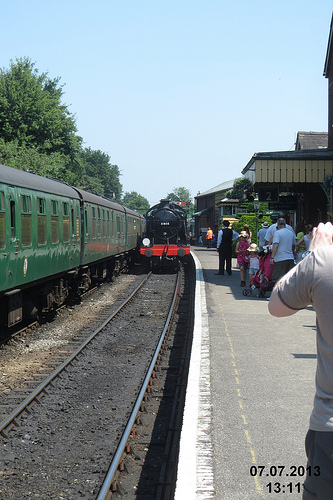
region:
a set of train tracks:
[0, 260, 181, 496]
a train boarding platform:
[173, 234, 329, 498]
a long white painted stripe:
[173, 245, 214, 496]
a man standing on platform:
[212, 219, 237, 272]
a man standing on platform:
[269, 217, 293, 283]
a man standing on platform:
[265, 223, 330, 497]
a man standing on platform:
[203, 226, 214, 246]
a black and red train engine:
[140, 198, 191, 274]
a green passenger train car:
[4, 163, 78, 337]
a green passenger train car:
[82, 188, 127, 289]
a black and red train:
[119, 178, 204, 295]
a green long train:
[0, 157, 166, 339]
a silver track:
[0, 246, 186, 498]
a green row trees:
[0, 45, 152, 228]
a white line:
[169, 237, 220, 497]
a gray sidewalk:
[208, 230, 330, 498]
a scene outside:
[17, 8, 328, 498]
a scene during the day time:
[14, 15, 327, 498]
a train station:
[190, 115, 331, 326]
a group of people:
[201, 209, 332, 317]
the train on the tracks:
[135, 175, 190, 283]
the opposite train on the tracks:
[0, 163, 138, 274]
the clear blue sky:
[147, 31, 228, 83]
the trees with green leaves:
[4, 75, 81, 171]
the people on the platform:
[218, 212, 328, 330]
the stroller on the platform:
[228, 246, 273, 295]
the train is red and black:
[139, 195, 184, 255]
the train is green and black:
[7, 165, 124, 268]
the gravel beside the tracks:
[0, 249, 158, 393]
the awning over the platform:
[236, 141, 331, 193]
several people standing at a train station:
[213, 199, 325, 308]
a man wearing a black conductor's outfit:
[214, 218, 240, 276]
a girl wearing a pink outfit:
[231, 229, 253, 290]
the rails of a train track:
[66, 286, 172, 488]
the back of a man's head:
[272, 215, 289, 233]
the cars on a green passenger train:
[13, 174, 138, 264]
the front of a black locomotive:
[135, 197, 196, 274]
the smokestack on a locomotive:
[158, 197, 172, 212]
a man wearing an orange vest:
[202, 225, 214, 248]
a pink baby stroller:
[240, 249, 270, 299]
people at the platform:
[208, 192, 317, 438]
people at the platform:
[246, 210, 307, 324]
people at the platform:
[223, 220, 304, 285]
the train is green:
[22, 171, 133, 285]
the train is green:
[32, 195, 83, 275]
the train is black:
[124, 200, 209, 282]